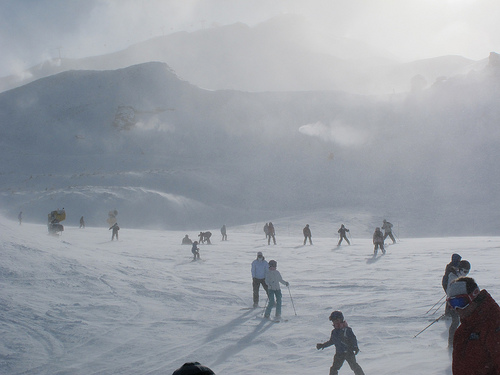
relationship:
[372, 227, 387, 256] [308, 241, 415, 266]
people skiing on snow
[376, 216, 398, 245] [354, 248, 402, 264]
person skiing on snow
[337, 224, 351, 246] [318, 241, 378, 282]
person skiing on snow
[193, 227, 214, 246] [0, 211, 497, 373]
person skiing on snow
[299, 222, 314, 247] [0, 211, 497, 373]
person skiing on snow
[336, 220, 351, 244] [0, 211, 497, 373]
person skiing on snow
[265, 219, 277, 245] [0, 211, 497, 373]
person skiing on snow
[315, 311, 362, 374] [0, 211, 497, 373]
child skiing on snow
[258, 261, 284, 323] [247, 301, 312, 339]
person skiing on snow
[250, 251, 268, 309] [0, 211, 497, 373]
person skiing on snow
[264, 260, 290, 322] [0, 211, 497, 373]
people skiing on snow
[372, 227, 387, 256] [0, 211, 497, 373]
people skiing on snow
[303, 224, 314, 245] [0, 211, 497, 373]
person skiing on snow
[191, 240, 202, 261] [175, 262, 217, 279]
children skiing on snow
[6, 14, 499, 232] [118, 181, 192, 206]
mountains covered in snow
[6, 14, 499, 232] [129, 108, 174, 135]
mountains covered in snow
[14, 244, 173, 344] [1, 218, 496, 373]
snow covered path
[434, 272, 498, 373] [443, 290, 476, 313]
man wearing goggles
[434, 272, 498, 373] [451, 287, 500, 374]
man wearing black coat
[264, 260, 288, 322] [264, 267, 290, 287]
person wearing coat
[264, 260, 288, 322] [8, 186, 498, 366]
person on hill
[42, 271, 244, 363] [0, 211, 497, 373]
tracks in snow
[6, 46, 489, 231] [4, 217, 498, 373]
mountains behind area